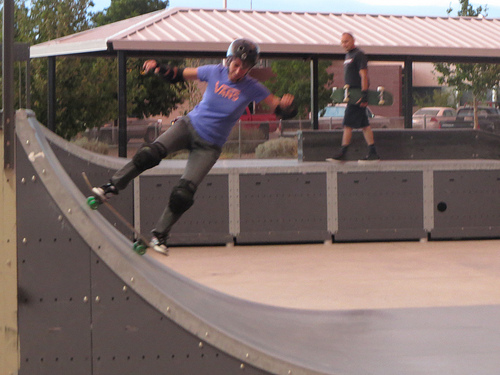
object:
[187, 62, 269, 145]
blue shirt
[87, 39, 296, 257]
woman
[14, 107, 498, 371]
skateboard ramp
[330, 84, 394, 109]
skateboard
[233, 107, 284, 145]
red pickup truck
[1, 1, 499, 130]
green trees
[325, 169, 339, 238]
large tan line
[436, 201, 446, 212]
black hole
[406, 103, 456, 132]
white car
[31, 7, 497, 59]
pink roof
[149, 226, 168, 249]
white sneaker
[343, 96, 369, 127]
black shorts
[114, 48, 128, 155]
long black pole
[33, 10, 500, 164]
pavillion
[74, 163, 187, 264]
board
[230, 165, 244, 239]
line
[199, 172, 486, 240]
base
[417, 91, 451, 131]
car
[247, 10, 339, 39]
stripes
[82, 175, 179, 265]
sneakers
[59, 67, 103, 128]
trees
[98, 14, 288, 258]
person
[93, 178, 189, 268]
shoes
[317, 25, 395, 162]
person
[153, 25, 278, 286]
girl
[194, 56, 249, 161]
shirt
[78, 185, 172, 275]
wheels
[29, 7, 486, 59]
roof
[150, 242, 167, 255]
soles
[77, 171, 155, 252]
skateboard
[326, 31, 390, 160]
man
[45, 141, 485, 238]
wall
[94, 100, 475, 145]
parking lot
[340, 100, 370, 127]
shorts